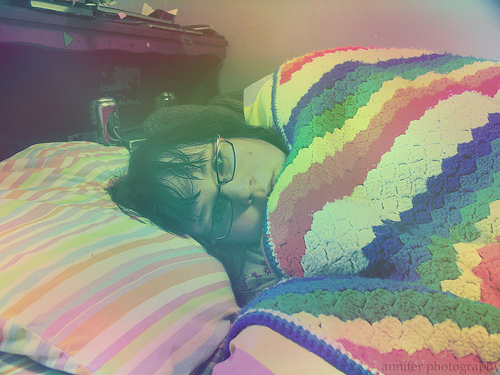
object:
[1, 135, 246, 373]
pillow case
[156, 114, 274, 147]
hair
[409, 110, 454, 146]
ground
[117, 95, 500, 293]
person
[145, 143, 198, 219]
hair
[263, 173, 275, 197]
lips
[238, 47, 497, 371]
sheet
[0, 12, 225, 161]
headboard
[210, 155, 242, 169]
floor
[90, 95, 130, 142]
can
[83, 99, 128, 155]
soda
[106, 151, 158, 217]
hair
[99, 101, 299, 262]
head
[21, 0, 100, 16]
paper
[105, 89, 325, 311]
girl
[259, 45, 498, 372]
bedspread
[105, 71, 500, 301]
girl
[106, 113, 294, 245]
head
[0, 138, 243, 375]
pillow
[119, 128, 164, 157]
clock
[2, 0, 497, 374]
bed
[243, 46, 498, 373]
blanket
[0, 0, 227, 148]
table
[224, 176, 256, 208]
nose